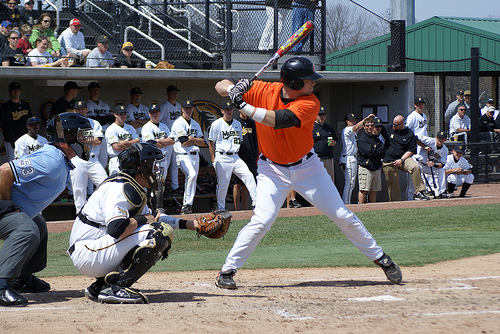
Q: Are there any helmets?
A: Yes, there is a helmet.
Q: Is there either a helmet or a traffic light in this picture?
A: Yes, there is a helmet.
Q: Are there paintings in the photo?
A: No, there are no paintings.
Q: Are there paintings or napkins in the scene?
A: No, there are no paintings or napkins.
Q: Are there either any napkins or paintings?
A: No, there are no paintings or napkins.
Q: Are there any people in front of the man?
A: Yes, there is a person in front of the man.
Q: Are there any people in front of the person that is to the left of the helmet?
A: Yes, there is a person in front of the man.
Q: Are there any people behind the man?
A: No, the person is in front of the man.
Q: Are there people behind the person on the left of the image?
A: No, the person is in front of the man.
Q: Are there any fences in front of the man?
A: No, there is a person in front of the man.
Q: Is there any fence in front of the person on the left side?
A: No, there is a person in front of the man.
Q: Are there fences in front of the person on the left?
A: No, there is a person in front of the man.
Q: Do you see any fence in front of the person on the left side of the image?
A: No, there is a person in front of the man.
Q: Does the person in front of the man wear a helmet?
A: Yes, the person wears a helmet.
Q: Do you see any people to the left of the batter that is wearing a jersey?
A: Yes, there is a person to the left of the batter.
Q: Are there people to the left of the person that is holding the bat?
A: Yes, there is a person to the left of the batter.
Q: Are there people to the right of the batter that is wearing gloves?
A: No, the person is to the left of the batter.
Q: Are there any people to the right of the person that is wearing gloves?
A: No, the person is to the left of the batter.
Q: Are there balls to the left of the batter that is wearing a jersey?
A: No, there is a person to the left of the batter.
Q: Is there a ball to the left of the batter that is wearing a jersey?
A: No, there is a person to the left of the batter.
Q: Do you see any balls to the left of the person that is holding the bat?
A: No, there is a person to the left of the batter.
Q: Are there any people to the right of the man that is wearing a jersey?
A: Yes, there is a person to the right of the man.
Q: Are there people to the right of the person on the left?
A: Yes, there is a person to the right of the man.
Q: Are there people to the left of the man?
A: No, the person is to the right of the man.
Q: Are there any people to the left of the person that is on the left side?
A: No, the person is to the right of the man.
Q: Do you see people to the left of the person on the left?
A: No, the person is to the right of the man.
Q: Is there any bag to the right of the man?
A: No, there is a person to the right of the man.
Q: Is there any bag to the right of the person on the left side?
A: No, there is a person to the right of the man.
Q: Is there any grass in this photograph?
A: Yes, there is grass.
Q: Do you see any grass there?
A: Yes, there is grass.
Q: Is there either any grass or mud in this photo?
A: Yes, there is grass.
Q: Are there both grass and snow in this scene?
A: No, there is grass but no snow.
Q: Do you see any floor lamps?
A: No, there are no floor lamps.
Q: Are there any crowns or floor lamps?
A: No, there are no floor lamps or crowns.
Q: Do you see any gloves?
A: Yes, there are gloves.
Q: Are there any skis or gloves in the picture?
A: Yes, there are gloves.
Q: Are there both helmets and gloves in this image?
A: Yes, there are both gloves and a helmet.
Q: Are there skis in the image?
A: No, there are no skis.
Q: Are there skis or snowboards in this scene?
A: No, there are no skis or snowboards.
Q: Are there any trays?
A: No, there are no trays.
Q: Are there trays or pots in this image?
A: No, there are no trays or pots.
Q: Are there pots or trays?
A: No, there are no trays or pots.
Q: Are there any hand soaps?
A: No, there are no hand soaps.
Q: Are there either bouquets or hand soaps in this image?
A: No, there are no hand soaps or bouquets.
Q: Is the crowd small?
A: Yes, the crowd is small.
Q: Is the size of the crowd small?
A: Yes, the crowd is small.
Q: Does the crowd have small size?
A: Yes, the crowd is small.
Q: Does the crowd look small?
A: Yes, the crowd is small.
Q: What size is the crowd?
A: The crowd is small.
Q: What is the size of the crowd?
A: The crowd is small.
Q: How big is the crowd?
A: The crowd is small.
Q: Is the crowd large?
A: No, the crowd is small.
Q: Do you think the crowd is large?
A: No, the crowd is small.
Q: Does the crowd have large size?
A: No, the crowd is small.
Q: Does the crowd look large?
A: No, the crowd is small.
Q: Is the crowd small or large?
A: The crowd is small.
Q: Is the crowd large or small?
A: The crowd is small.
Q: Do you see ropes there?
A: No, there are no ropes.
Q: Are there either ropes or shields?
A: No, there are no ropes or shields.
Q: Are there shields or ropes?
A: No, there are no ropes or shields.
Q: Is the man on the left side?
A: Yes, the man is on the left of the image.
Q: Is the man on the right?
A: No, the man is on the left of the image.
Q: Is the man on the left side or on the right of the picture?
A: The man is on the left of the image.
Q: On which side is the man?
A: The man is on the left of the image.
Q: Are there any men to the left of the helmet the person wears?
A: Yes, there is a man to the left of the helmet.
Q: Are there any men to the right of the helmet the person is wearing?
A: No, the man is to the left of the helmet.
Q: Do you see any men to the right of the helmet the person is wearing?
A: No, the man is to the left of the helmet.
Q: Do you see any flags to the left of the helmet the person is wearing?
A: No, there is a man to the left of the helmet.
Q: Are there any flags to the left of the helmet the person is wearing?
A: No, there is a man to the left of the helmet.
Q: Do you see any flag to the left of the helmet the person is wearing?
A: No, there is a man to the left of the helmet.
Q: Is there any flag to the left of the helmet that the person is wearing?
A: No, there is a man to the left of the helmet.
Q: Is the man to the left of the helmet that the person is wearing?
A: Yes, the man is to the left of the helmet.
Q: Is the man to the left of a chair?
A: No, the man is to the left of the helmet.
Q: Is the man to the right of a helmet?
A: No, the man is to the left of a helmet.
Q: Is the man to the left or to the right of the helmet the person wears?
A: The man is to the left of the helmet.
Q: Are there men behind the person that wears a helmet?
A: Yes, there is a man behind the person.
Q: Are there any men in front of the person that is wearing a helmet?
A: No, the man is behind the person.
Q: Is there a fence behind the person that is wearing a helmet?
A: No, there is a man behind the person.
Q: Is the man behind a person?
A: Yes, the man is behind a person.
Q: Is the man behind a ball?
A: No, the man is behind a person.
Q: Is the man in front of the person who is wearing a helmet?
A: No, the man is behind the person.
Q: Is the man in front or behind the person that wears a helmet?
A: The man is behind the person.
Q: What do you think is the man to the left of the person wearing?
A: The man is wearing a jersey.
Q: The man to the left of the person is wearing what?
A: The man is wearing a jersey.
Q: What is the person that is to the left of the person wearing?
A: The man is wearing a jersey.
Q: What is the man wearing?
A: The man is wearing a jersey.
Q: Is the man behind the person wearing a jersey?
A: Yes, the man is wearing a jersey.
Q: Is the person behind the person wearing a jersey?
A: Yes, the man is wearing a jersey.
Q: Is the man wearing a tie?
A: No, the man is wearing a jersey.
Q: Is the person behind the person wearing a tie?
A: No, the man is wearing a jersey.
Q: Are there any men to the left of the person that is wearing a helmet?
A: Yes, there is a man to the left of the person.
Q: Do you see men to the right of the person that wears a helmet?
A: No, the man is to the left of the person.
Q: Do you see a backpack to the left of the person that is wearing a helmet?
A: No, there is a man to the left of the person.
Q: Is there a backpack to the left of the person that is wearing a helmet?
A: No, there is a man to the left of the person.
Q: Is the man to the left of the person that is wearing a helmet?
A: Yes, the man is to the left of the person.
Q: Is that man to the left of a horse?
A: No, the man is to the left of the person.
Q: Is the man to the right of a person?
A: No, the man is to the left of a person.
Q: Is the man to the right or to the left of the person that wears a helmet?
A: The man is to the left of the person.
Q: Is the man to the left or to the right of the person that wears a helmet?
A: The man is to the left of the person.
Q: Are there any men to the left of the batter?
A: Yes, there is a man to the left of the batter.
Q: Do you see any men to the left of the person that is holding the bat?
A: Yes, there is a man to the left of the batter.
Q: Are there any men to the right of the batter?
A: No, the man is to the left of the batter.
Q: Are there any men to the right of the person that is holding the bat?
A: No, the man is to the left of the batter.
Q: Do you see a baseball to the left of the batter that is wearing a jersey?
A: No, there is a man to the left of the batter.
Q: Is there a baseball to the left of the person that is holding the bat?
A: No, there is a man to the left of the batter.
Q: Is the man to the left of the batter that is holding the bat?
A: Yes, the man is to the left of the batter.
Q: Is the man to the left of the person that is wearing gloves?
A: Yes, the man is to the left of the batter.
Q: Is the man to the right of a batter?
A: No, the man is to the left of a batter.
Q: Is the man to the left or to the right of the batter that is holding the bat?
A: The man is to the left of the batter.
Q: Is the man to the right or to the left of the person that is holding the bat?
A: The man is to the left of the batter.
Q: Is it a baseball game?
A: Yes, this is a baseball game.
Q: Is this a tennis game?
A: No, this is a baseball game.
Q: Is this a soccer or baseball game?
A: This is a baseball game.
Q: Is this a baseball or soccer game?
A: This is a baseball game.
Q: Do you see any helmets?
A: Yes, there is a helmet.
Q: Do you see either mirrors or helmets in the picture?
A: Yes, there is a helmet.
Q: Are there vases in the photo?
A: No, there are no vases.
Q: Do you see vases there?
A: No, there are no vases.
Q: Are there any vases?
A: No, there are no vases.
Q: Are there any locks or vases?
A: No, there are no vases or locks.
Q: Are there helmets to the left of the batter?
A: Yes, there is a helmet to the left of the batter.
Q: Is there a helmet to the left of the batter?
A: Yes, there is a helmet to the left of the batter.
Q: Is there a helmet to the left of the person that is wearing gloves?
A: Yes, there is a helmet to the left of the batter.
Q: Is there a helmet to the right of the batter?
A: No, the helmet is to the left of the batter.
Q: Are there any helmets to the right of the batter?
A: No, the helmet is to the left of the batter.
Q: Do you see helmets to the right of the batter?
A: No, the helmet is to the left of the batter.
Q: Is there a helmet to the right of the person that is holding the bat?
A: No, the helmet is to the left of the batter.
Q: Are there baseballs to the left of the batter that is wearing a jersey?
A: No, there is a helmet to the left of the batter.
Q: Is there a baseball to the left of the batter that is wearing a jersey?
A: No, there is a helmet to the left of the batter.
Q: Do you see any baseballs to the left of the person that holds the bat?
A: No, there is a helmet to the left of the batter.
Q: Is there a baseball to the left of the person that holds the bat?
A: No, there is a helmet to the left of the batter.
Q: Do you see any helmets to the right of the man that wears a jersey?
A: Yes, there is a helmet to the right of the man.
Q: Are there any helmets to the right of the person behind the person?
A: Yes, there is a helmet to the right of the man.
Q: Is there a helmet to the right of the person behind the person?
A: Yes, there is a helmet to the right of the man.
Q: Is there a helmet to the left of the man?
A: No, the helmet is to the right of the man.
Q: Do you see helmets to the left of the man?
A: No, the helmet is to the right of the man.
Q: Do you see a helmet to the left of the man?
A: No, the helmet is to the right of the man.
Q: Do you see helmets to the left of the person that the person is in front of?
A: No, the helmet is to the right of the man.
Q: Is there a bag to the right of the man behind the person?
A: No, there is a helmet to the right of the man.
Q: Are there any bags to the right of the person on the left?
A: No, there is a helmet to the right of the man.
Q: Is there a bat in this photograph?
A: Yes, there is a bat.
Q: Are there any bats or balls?
A: Yes, there is a bat.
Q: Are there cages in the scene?
A: No, there are no cages.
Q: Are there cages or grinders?
A: No, there are no cages or grinders.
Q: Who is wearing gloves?
A: The batter is wearing gloves.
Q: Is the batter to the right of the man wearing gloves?
A: Yes, the batter is wearing gloves.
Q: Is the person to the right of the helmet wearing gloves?
A: Yes, the batter is wearing gloves.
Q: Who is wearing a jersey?
A: The batter is wearing a jersey.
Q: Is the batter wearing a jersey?
A: Yes, the batter is wearing a jersey.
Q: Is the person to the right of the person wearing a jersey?
A: Yes, the batter is wearing a jersey.